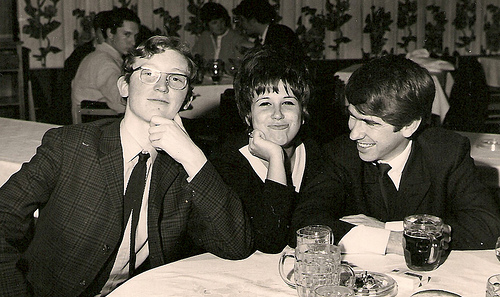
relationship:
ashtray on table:
[339, 262, 388, 294] [208, 229, 471, 295]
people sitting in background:
[60, 52, 297, 61] [5, 113, 498, 123]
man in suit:
[90, 48, 185, 193] [40, 141, 105, 265]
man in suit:
[340, 49, 437, 203] [321, 149, 425, 198]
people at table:
[70, 46, 411, 209] [173, 268, 215, 294]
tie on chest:
[110, 150, 164, 262] [80, 142, 176, 240]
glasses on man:
[90, 30, 212, 129] [99, 49, 181, 221]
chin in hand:
[251, 122, 339, 169] [243, 132, 278, 172]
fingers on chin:
[149, 128, 165, 140] [122, 103, 166, 133]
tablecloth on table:
[154, 268, 217, 293] [189, 264, 251, 294]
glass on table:
[394, 221, 446, 267] [200, 250, 225, 269]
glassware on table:
[290, 221, 336, 281] [106, 245, 499, 297]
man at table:
[0, 36, 251, 297] [198, 267, 260, 295]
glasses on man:
[121, 63, 193, 91] [113, 39, 178, 192]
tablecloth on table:
[183, 275, 220, 287] [190, 269, 228, 284]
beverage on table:
[400, 219, 439, 274] [193, 273, 233, 284]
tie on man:
[110, 150, 158, 272] [82, 41, 178, 224]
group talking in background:
[60, 0, 312, 121] [1, 1, 484, 141]